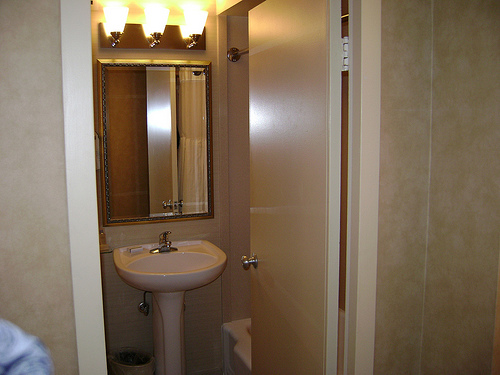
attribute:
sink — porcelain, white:
[111, 239, 229, 375]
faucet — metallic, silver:
[160, 229, 173, 247]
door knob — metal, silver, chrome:
[241, 252, 259, 272]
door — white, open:
[247, 1, 337, 375]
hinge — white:
[341, 35, 349, 73]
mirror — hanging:
[103, 64, 209, 220]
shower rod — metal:
[226, 12, 349, 64]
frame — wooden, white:
[341, 2, 382, 374]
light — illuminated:
[184, 6, 210, 37]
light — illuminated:
[142, 4, 170, 41]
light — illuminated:
[102, 2, 130, 35]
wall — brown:
[92, 2, 223, 374]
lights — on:
[97, 3, 210, 46]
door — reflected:
[145, 65, 181, 221]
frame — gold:
[96, 57, 219, 227]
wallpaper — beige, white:
[375, 7, 500, 375]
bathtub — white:
[221, 308, 345, 374]